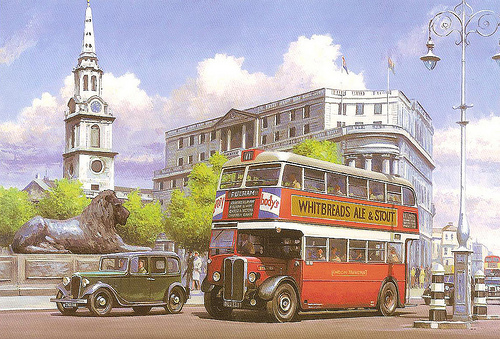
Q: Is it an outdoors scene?
A: Yes, it is outdoors.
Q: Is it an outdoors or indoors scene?
A: It is outdoors.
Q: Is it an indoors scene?
A: No, it is outdoors.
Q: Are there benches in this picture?
A: No, there are no benches.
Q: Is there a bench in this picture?
A: No, there are no benches.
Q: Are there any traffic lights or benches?
A: No, there are no benches or traffic lights.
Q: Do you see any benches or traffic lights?
A: No, there are no benches or traffic lights.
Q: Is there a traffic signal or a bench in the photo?
A: No, there are no benches or traffic lights.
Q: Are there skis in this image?
A: No, there are no skis.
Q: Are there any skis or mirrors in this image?
A: No, there are no skis or mirrors.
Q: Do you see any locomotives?
A: No, there are no locomotives.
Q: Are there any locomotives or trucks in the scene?
A: No, there are no locomotives or trucks.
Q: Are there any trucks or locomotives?
A: No, there are no locomotives or trucks.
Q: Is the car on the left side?
A: Yes, the car is on the left of the image.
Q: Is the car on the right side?
A: No, the car is on the left of the image.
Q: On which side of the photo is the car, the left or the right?
A: The car is on the left of the image.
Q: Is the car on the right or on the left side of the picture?
A: The car is on the left of the image.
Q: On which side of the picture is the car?
A: The car is on the left of the image.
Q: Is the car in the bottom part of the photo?
A: Yes, the car is in the bottom of the image.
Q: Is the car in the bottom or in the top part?
A: The car is in the bottom of the image.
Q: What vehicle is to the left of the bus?
A: The vehicle is a car.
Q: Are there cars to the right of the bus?
A: No, the car is to the left of the bus.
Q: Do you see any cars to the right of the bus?
A: No, the car is to the left of the bus.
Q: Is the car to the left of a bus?
A: Yes, the car is to the left of a bus.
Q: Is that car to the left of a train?
A: No, the car is to the left of a bus.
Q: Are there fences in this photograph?
A: No, there are no fences.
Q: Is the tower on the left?
A: Yes, the tower is on the left of the image.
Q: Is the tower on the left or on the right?
A: The tower is on the left of the image.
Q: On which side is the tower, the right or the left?
A: The tower is on the left of the image.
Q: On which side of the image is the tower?
A: The tower is on the left of the image.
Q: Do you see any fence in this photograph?
A: No, there are no fences.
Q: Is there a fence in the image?
A: No, there are no fences.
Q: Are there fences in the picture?
A: No, there are no fences.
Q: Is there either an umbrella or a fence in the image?
A: No, there are no fences or umbrellas.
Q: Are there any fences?
A: No, there are no fences.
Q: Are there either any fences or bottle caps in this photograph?
A: No, there are no fences or bottle caps.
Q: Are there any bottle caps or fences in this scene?
A: No, there are no fences or bottle caps.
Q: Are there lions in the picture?
A: Yes, there is a lion.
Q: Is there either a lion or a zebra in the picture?
A: Yes, there is a lion.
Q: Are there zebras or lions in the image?
A: Yes, there is a lion.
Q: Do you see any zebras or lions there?
A: Yes, there is a lion.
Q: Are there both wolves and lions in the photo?
A: No, there is a lion but no wolves.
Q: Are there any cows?
A: No, there are no cows.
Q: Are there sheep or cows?
A: No, there are no cows or sheep.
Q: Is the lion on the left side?
A: Yes, the lion is on the left of the image.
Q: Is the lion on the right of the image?
A: No, the lion is on the left of the image.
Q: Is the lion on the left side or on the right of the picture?
A: The lion is on the left of the image.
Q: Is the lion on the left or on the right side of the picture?
A: The lion is on the left of the image.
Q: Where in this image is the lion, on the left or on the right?
A: The lion is on the left of the image.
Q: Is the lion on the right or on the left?
A: The lion is on the left of the image.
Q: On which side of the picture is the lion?
A: The lion is on the left of the image.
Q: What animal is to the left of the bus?
A: The animal is a lion.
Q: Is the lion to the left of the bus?
A: Yes, the lion is to the left of the bus.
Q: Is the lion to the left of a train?
A: No, the lion is to the left of the bus.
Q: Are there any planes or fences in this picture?
A: No, there are no fences or planes.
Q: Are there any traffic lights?
A: No, there are no traffic lights.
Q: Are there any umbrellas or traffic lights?
A: No, there are no traffic lights or umbrellas.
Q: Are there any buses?
A: Yes, there is a bus.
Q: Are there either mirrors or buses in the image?
A: Yes, there is a bus.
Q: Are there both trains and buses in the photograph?
A: No, there is a bus but no trains.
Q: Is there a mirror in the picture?
A: No, there are no mirrors.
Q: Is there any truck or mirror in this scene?
A: No, there are no mirrors or trucks.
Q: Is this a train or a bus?
A: This is a bus.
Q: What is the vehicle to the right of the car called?
A: The vehicle is a bus.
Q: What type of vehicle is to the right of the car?
A: The vehicle is a bus.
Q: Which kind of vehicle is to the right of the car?
A: The vehicle is a bus.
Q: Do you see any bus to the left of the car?
A: No, the bus is to the right of the car.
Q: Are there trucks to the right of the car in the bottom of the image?
A: No, there is a bus to the right of the car.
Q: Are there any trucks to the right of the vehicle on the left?
A: No, there is a bus to the right of the car.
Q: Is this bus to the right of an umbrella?
A: No, the bus is to the right of the car.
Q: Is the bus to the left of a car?
A: No, the bus is to the right of a car.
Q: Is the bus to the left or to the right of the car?
A: The bus is to the right of the car.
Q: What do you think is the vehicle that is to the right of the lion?
A: The vehicle is a bus.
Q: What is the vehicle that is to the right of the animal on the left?
A: The vehicle is a bus.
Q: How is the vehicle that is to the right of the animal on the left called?
A: The vehicle is a bus.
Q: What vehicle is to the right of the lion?
A: The vehicle is a bus.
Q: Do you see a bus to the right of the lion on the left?
A: Yes, there is a bus to the right of the lion.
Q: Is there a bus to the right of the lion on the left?
A: Yes, there is a bus to the right of the lion.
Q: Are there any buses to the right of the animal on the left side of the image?
A: Yes, there is a bus to the right of the lion.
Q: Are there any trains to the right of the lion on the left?
A: No, there is a bus to the right of the lion.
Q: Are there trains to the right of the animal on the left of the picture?
A: No, there is a bus to the right of the lion.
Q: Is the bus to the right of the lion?
A: Yes, the bus is to the right of the lion.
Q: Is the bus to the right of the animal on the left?
A: Yes, the bus is to the right of the lion.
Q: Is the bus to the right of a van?
A: No, the bus is to the right of the lion.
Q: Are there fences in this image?
A: No, there are no fences.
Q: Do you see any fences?
A: No, there are no fences.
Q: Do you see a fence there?
A: No, there are no fences.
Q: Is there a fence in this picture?
A: No, there are no fences.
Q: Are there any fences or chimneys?
A: No, there are no fences or chimneys.